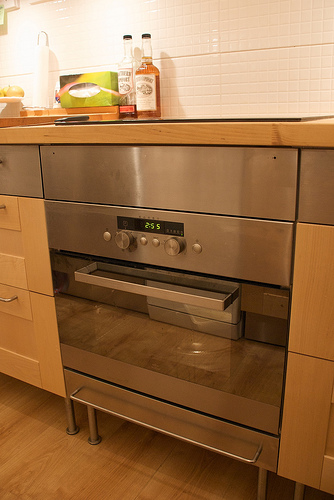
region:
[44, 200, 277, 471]
Built in kitchen oven.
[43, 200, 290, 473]
Built in stainless steel oven.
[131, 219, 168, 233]
Digital clock on oven.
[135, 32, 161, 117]
Bottle of liquor with amber liquid in it.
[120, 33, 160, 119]
Two bottles of liquor.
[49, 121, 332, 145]
Wooden kitchen work surface.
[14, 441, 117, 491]
Wooden laminate flooring.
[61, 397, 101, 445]
Metal legs of cabinetry.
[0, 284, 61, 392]
Wooden cabinet with metal pull.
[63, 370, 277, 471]
Under oven drawer with metal handle.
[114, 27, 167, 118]
two bottles on the counter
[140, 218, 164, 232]
green numbers on the display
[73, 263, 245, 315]
handle on the oven door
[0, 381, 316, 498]
light brown wood on the floor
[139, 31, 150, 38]
black cap on the bottle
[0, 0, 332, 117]
white tiles on the wall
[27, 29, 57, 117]
roll of paper towels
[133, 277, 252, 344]
reflection in the window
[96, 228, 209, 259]
a row of knobs and buttons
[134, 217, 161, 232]
digital time display with green numbers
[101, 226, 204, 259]
oven buttons and dials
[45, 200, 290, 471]
modern style stainless steel oven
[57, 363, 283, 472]
bread warmer or storage comparment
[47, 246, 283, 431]
oven door reflecting the kitchen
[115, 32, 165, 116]
bottles on the kitchen counter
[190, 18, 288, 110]
back splash tiles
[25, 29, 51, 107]
paper towels on a holder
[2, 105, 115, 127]
wooden cutting board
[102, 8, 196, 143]
bottles of liquor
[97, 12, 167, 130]
bottles of hard liquor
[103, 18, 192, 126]
bottles of whiskey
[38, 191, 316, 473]
this is an oven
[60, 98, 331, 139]
an electric stove top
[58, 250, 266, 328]
the oven handle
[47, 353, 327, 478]
the broiler drawer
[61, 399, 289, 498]
the oven is raised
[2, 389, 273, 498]
this is a wood floor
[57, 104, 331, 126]
a cooktop in a kitchen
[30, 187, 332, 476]
an oven between the cupboards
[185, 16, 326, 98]
white tile on the wall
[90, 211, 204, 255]
controls for an oven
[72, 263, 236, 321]
a handle for an oven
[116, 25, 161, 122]
two bottles of whiskey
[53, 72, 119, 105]
a box of tissue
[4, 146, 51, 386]
drawers in a kitchen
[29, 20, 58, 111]
a roll of paper towel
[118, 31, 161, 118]
two clear bottles on a counter top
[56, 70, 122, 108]
a box of tissues on a counter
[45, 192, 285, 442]
a silver oven with a door handle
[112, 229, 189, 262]
control buttons on a oven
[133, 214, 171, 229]
a digital clock on a oven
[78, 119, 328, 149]
a wood counter top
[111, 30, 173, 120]
liquor bottles on range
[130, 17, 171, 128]
brown liquor in bottle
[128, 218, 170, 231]
green numbers on range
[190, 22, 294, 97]
white tile on wall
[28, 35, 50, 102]
white towels on rack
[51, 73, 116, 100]
latex gloves in box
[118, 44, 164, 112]
two bottles on table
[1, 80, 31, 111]
fruit sitting near towels